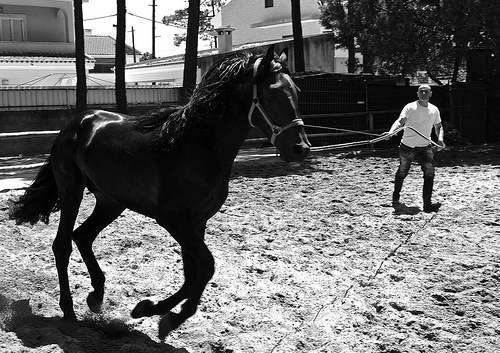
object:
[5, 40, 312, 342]
horse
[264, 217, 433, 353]
shadow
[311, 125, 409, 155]
rope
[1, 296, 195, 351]
shadow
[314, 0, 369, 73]
tree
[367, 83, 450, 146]
fence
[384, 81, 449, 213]
man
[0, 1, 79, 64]
building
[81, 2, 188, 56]
sky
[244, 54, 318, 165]
harness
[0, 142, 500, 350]
field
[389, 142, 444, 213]
pants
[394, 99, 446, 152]
shirt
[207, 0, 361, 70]
house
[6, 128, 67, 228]
tail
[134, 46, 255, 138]
mane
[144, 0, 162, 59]
line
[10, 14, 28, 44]
window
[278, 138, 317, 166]
nose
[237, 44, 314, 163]
head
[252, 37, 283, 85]
ear